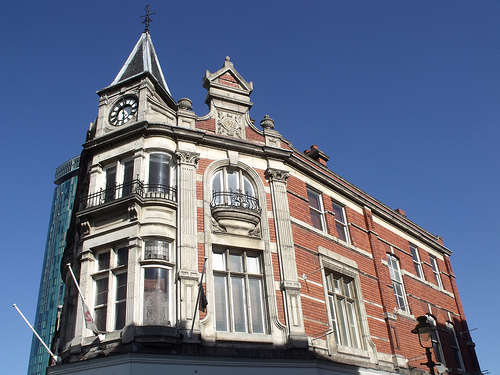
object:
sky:
[0, 0, 499, 373]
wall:
[287, 166, 484, 375]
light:
[408, 323, 430, 340]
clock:
[106, 94, 139, 127]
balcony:
[213, 191, 263, 237]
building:
[66, 0, 481, 373]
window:
[310, 210, 326, 233]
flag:
[199, 285, 207, 311]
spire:
[267, 169, 308, 347]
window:
[231, 274, 248, 334]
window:
[146, 266, 170, 326]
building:
[30, 155, 80, 375]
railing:
[79, 179, 179, 209]